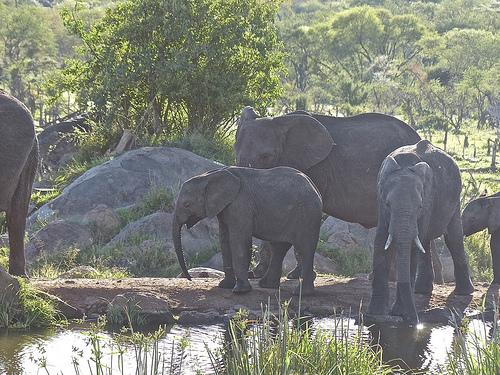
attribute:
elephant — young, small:
[172, 164, 324, 295]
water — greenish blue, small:
[1, 321, 498, 373]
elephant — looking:
[369, 138, 472, 312]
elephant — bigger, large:
[235, 105, 434, 296]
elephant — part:
[0, 78, 38, 279]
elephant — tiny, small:
[462, 193, 499, 289]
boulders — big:
[24, 152, 476, 279]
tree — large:
[60, 0, 283, 139]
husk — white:
[413, 235, 426, 254]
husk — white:
[383, 234, 393, 249]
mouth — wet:
[184, 215, 202, 230]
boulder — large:
[32, 146, 329, 266]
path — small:
[33, 274, 499, 312]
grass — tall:
[217, 299, 388, 374]